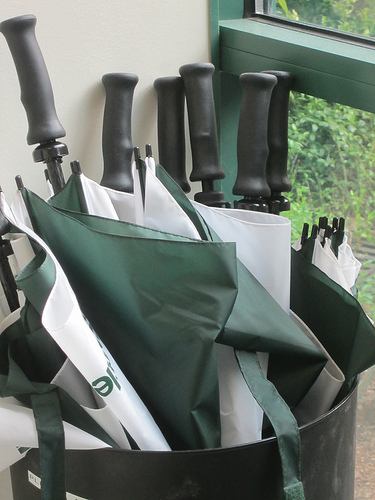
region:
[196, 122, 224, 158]
part of a handle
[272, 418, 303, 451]
part of a ribbon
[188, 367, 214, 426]
part of a cloth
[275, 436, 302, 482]
part of a ribbon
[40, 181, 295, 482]
Umbrella in the garbage can.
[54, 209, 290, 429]
Umbrellas is green and white.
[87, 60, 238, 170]
The handle on umbrella is black.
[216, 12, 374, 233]
Umbrella next to window.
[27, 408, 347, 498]
Garbage can is black.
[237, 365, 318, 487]
Strap on umbrella is green.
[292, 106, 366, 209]
Trees outside the window.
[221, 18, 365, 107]
Window pane is green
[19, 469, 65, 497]
Label on the can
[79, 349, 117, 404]
Writing on the umbrella.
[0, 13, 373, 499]
umbrellas grouped together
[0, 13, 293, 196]
black handles on the umbrellas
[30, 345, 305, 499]
green straps on umbrellas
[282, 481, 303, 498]
velcro on strap of umbrella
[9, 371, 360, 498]
umbrellas in black bin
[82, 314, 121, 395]
green lettering on umbrella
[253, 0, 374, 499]
windows behind umbrellas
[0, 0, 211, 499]
white wall behind umbrellas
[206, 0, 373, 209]
green window frame behind umbrella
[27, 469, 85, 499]
white label on black bin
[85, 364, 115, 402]
An e on the umbrella.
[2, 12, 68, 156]
The handle is black.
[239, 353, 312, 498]
The fastening string is green.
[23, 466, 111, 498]
A tag on the barrel.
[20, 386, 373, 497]
The barrel is black.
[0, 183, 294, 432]
The umbrellas are green and white.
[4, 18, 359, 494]
The umbrellas are in a barrel.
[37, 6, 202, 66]
The wall is white.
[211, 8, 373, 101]
The window sill is green.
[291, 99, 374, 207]
The leaves are green.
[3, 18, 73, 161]
The handle is black.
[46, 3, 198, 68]
The wall is white.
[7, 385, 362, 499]
The barrel is black.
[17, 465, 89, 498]
Sticker on the barrel.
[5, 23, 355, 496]
Umbrellas are in the barrel.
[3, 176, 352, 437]
The umbrellas are green and white.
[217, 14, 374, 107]
The window sill is green.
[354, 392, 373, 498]
The ground is brown.